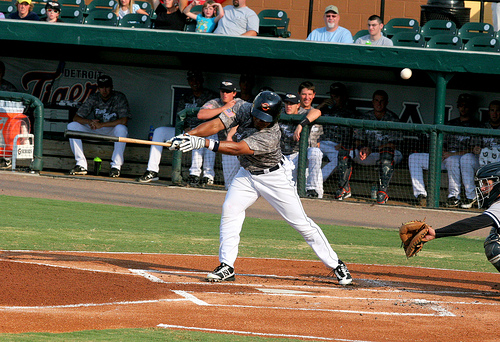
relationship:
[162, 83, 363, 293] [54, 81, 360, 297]
player of baseball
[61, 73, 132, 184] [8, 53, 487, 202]
player in dugout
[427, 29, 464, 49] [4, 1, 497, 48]
seat in audience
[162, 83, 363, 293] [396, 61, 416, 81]
man playing baseball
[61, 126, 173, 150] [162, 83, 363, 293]
bat held by player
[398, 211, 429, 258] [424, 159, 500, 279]
mitt of catcher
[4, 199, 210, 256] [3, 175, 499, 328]
grass on field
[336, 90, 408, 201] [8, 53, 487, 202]
man sitting in dugout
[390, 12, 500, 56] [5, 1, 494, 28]
chairs in background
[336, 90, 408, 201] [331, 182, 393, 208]
man wearing shoes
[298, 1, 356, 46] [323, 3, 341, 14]
man wears hat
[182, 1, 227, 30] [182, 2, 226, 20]
girl with arms up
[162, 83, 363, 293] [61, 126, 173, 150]
player swinging h bat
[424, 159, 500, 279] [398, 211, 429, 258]
catcher holding out glove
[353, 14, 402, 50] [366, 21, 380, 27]
boy wearing sunglasses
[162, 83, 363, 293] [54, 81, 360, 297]
man hitting baseball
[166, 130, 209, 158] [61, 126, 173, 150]
hands holding bat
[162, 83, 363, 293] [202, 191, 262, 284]
batter has right foot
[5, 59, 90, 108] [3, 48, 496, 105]
logo in background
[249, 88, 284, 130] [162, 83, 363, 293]
helmet on a batter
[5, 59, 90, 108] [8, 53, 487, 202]
logo in dugout